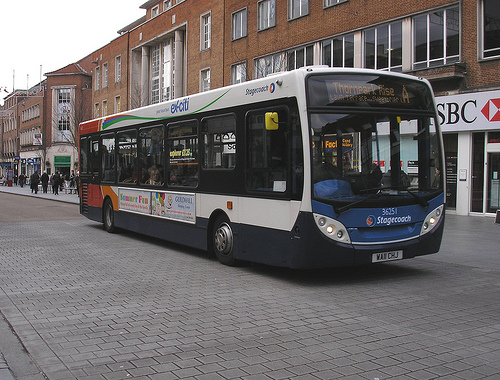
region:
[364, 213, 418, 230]
LOGO NAME OF BUS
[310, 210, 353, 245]
HEADLIGHTS ON FRONT OF BUS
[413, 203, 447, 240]
HEADLIGHTS ON FRONT OF BUS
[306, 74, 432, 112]
DESIGNATION SIGN FOR BUS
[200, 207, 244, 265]
FRONT WHEEL OF BUS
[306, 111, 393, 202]
FRONT WINDSHIEL OF BUS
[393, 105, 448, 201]
FRONT WINDSHIELD OF BUS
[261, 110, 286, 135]
SIDE VIEW MIRROR OF BUS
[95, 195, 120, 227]
REAR TIRE OF BUS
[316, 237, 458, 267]
BUMPER AREA OF BUS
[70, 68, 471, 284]
a giant white tour bus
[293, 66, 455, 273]
the front of a tour bus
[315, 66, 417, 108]
the front sign of a tour bus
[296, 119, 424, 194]
the front window of a tour bus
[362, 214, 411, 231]
the front logo of a tour bus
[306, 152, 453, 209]
the front windshield wipers of a tour bus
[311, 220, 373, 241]
the front light of a tour bus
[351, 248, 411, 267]
the front license plate of a tour bus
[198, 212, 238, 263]
the wheel of a tour bus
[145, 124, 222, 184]
the window of a tour bus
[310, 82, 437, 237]
front windshield of bus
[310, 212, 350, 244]
front lights on bus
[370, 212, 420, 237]
white writing on front of bus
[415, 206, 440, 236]
white writing on front of bus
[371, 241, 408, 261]
white licence plate on bus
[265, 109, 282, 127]
yellow side view mirror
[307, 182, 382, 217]
window wipers on front of bus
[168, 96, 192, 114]
blue writing on side of bus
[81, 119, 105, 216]
red paint on back of bus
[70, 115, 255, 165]
windows on side of bus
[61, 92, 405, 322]
bus driving down the road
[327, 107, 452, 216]
windshield on the bus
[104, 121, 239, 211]
windows on the bus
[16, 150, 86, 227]
people walking on the sidewalk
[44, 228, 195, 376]
road is made of bricks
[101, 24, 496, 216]
buildings next to the road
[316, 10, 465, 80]
windows on the buildings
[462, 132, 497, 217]
door on the building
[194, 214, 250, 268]
tires on the bus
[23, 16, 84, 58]
the sky is white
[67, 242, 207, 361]
The ground is made of concrete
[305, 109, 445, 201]
The windshield on the bus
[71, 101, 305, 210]
The side windows on the bus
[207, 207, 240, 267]
The front tire of the bus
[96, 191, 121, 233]
The back tire of the bus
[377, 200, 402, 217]
The numbers on the bus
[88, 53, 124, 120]
The windows on the side of the building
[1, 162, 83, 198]
The people on the sidewalk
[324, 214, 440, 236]
The headlights on the bus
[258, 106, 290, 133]
The rear view mirror on the bus